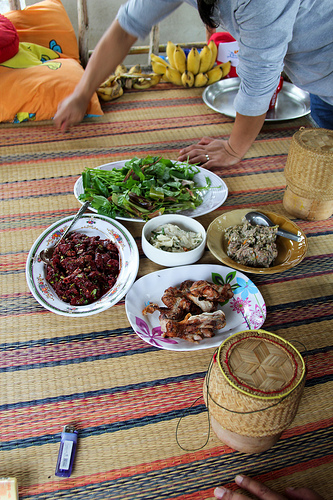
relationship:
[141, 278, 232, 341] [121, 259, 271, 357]
chicken in bowl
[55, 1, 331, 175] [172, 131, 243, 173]
person has hand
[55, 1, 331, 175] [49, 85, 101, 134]
person has hand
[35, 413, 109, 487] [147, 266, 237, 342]
lighter near food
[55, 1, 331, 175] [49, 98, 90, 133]
person has hand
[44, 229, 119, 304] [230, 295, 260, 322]
food in plate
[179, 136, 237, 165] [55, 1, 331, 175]
hand of person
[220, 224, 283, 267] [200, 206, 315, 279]
food in a bowl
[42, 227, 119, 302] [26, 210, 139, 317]
food in a bowl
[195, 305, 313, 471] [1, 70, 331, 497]
basket on ground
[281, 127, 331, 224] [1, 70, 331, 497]
basket on ground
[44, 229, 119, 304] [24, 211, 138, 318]
food on bowl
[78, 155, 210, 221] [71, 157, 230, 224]
food on plate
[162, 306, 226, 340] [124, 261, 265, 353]
chicken on bowl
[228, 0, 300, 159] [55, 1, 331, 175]
arm of person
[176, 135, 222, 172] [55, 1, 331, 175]
fingers of a person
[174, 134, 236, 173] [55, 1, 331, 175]
hand of a person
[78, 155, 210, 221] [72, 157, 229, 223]
food in plate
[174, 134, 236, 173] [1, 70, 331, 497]
hand on ground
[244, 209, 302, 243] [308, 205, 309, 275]
spoon in bowl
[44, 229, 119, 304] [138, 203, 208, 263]
food in bowl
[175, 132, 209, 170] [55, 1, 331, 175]
fingers on person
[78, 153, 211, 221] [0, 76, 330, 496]
food on floor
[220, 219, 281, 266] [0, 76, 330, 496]
food on floor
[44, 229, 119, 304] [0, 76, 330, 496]
food on floor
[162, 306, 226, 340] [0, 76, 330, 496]
chicken on floor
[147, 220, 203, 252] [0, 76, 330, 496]
food on floor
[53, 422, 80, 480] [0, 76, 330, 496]
lighter on floor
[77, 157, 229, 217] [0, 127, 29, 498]
plate on table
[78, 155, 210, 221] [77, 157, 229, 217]
food on plate